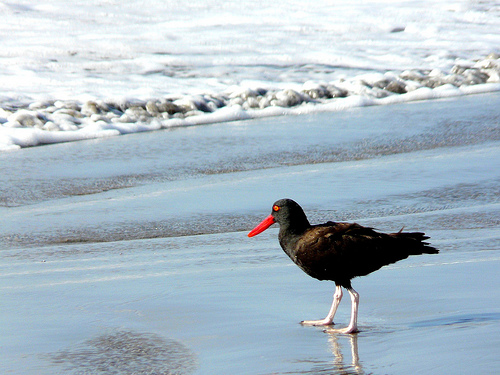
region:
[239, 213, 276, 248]
the beak of a bird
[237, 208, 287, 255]
a bird with a red beak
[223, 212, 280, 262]
the red beak on a bird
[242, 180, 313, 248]
the head of a bird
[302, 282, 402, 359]
the feet of a bird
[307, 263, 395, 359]
the legs of a bird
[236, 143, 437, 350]
a bird standing on sand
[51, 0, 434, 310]
a bird near water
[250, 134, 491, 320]
a black bird on th beach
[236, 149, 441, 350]
the black feathers of a bird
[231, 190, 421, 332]
the bird is black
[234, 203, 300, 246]
bird's beak is red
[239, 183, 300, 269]
bird's beak is red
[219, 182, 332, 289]
bird's beak is red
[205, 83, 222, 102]
white wave in ocean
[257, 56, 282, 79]
white wave in ocean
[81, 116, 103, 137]
white wave in ocean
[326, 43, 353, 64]
white wave in ocean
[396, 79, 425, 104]
white wave in ocean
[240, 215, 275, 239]
beak of the bird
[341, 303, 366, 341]
leg of the bird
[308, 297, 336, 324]
leg of the bird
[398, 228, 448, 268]
tail of the bird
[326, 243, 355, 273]
wing of the bird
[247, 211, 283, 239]
red beak on a bird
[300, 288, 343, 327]
leg of a bird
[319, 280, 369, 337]
leg of a bird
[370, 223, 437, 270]
tailfeathers of a bird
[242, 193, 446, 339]
bird on a beach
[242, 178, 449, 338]
bird with black feathers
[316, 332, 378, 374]
reflection of birds legs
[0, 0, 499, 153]
foamy water of the ocean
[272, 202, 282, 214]
red eye of a bird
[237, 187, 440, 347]
bird with red beak and red eyes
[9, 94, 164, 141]
some foamy white water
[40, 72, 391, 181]
ocean water receding from the beach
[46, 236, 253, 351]
a layer of water over the sand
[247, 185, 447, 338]
a bird on the beach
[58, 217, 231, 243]
ripples in the water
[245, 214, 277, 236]
a bright red beak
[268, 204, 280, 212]
an orange and red eye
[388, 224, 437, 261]
some long tail feathers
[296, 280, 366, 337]
a pair of white legs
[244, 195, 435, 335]
a black and brown bird